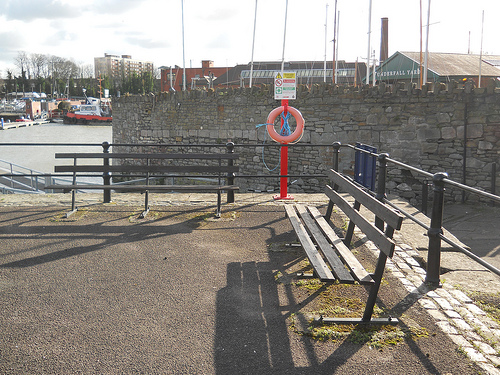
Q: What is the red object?
A: It is a sign indicating what "not to do" in these surroundings.